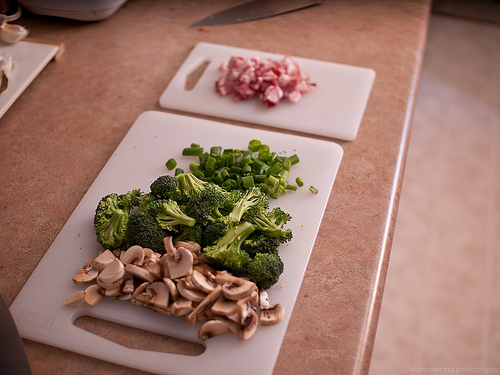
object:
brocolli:
[91, 193, 131, 250]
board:
[6, 111, 343, 375]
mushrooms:
[62, 288, 87, 311]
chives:
[163, 157, 178, 171]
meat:
[283, 85, 300, 102]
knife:
[209, 2, 321, 26]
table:
[0, 0, 428, 374]